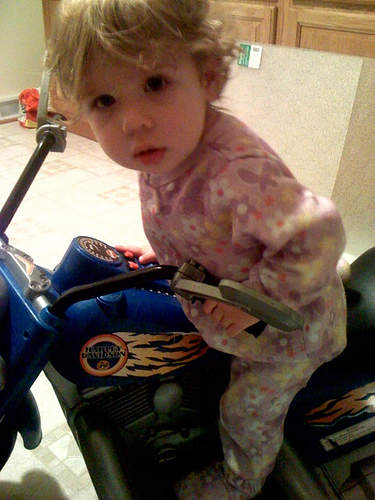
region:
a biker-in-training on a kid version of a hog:
[27, 1, 344, 494]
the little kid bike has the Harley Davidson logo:
[72, 326, 217, 384]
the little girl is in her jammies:
[110, 106, 347, 499]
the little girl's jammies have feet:
[170, 456, 286, 498]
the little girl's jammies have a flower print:
[133, 104, 353, 369]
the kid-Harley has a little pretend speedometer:
[67, 233, 164, 286]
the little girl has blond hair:
[43, 1, 230, 102]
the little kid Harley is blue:
[0, 230, 373, 430]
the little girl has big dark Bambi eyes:
[87, 69, 175, 112]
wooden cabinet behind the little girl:
[40, 1, 372, 141]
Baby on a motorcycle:
[45, 12, 338, 485]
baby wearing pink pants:
[198, 333, 314, 469]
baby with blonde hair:
[8, 0, 244, 92]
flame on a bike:
[76, 313, 213, 376]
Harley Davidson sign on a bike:
[70, 329, 133, 377]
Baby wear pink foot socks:
[169, 462, 240, 495]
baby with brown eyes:
[76, 74, 196, 117]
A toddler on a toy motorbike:
[2, 3, 372, 496]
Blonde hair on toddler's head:
[44, 1, 243, 176]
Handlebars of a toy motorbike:
[0, 117, 311, 339]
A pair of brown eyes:
[88, 71, 171, 111]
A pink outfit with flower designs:
[133, 105, 353, 483]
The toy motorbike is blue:
[1, 66, 372, 496]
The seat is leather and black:
[300, 245, 372, 371]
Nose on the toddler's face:
[113, 106, 159, 140]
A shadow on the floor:
[1, 469, 73, 497]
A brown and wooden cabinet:
[212, 2, 372, 59]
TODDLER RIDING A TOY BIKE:
[11, 9, 373, 493]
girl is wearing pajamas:
[106, 148, 367, 483]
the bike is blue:
[0, 234, 146, 441]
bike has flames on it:
[71, 312, 239, 419]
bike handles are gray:
[173, 253, 313, 359]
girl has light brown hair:
[24, 3, 280, 106]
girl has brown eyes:
[67, 80, 133, 134]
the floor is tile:
[24, 116, 142, 232]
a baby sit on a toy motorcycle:
[3, 3, 373, 498]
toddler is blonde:
[23, 0, 328, 265]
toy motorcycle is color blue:
[7, 120, 373, 492]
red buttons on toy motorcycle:
[114, 237, 144, 275]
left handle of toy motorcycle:
[33, 93, 69, 136]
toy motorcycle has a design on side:
[76, 327, 206, 390]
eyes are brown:
[70, 71, 187, 116]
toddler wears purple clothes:
[23, 9, 364, 494]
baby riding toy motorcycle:
[1, 0, 374, 498]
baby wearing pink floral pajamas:
[45, 0, 348, 498]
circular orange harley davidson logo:
[76, 332, 128, 377]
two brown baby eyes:
[91, 71, 169, 110]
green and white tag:
[236, 42, 262, 69]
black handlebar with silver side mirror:
[48, 256, 305, 333]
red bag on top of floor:
[16, 85, 42, 130]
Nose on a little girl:
[118, 98, 154, 135]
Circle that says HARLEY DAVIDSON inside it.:
[79, 335, 129, 376]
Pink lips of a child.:
[130, 142, 166, 166]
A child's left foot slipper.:
[171, 459, 267, 498]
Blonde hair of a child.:
[47, 0, 244, 121]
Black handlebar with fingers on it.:
[191, 292, 268, 337]